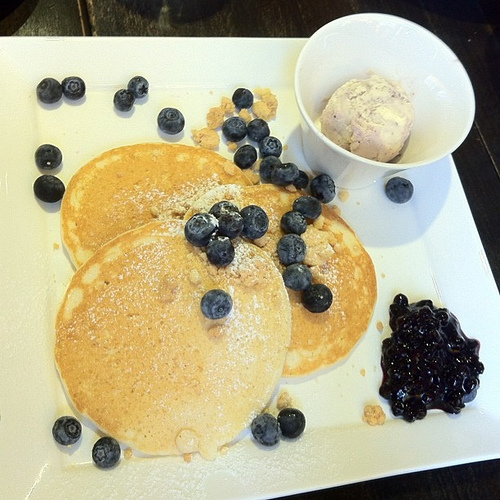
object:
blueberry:
[92, 437, 120, 468]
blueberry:
[52, 416, 80, 445]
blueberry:
[251, 412, 281, 445]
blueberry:
[201, 289, 232, 319]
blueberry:
[33, 175, 63, 202]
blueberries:
[35, 77, 63, 104]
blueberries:
[112, 89, 135, 110]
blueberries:
[156, 107, 185, 134]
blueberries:
[34, 144, 62, 168]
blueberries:
[233, 86, 255, 111]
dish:
[0, 35, 500, 500]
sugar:
[222, 183, 240, 201]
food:
[33, 77, 481, 470]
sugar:
[192, 91, 234, 152]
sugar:
[151, 173, 240, 219]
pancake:
[61, 145, 256, 271]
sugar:
[219, 279, 273, 404]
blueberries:
[280, 263, 312, 291]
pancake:
[51, 215, 293, 460]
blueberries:
[379, 293, 482, 424]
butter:
[319, 76, 415, 162]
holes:
[150, 333, 166, 342]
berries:
[126, 77, 149, 100]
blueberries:
[216, 208, 244, 238]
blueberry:
[386, 175, 416, 204]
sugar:
[150, 473, 202, 493]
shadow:
[283, 124, 451, 252]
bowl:
[294, 11, 475, 193]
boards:
[0, 0, 500, 291]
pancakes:
[58, 133, 259, 273]